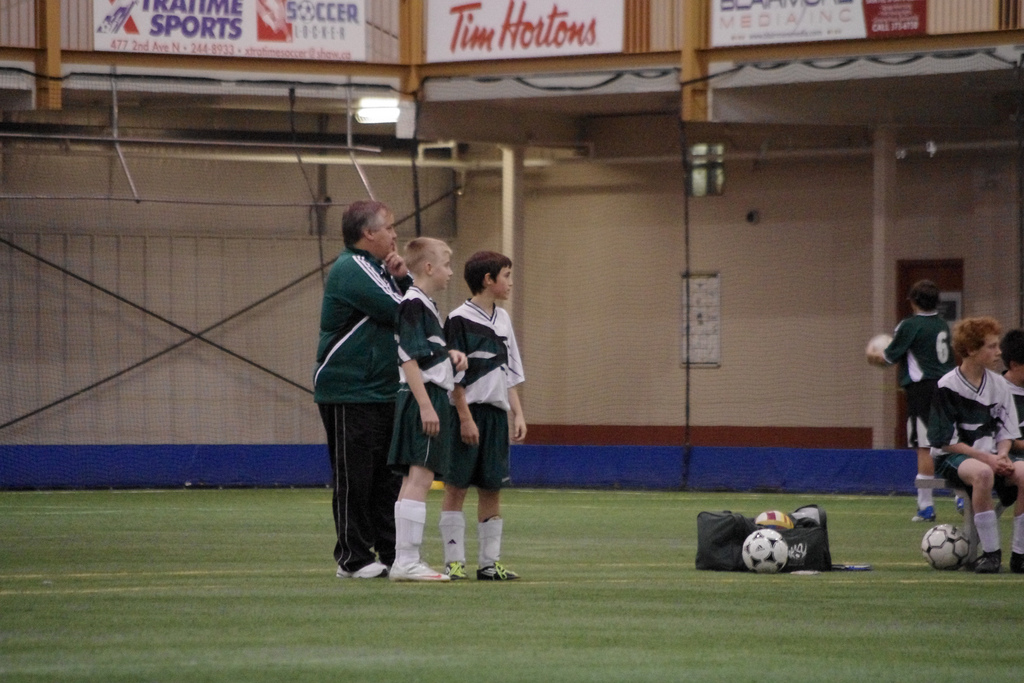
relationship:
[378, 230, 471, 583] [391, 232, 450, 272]
boy has hair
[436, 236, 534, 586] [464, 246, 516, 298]
boy has hair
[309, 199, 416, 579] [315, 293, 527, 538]
man wears uniforms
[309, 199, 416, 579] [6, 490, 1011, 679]
man in soccer field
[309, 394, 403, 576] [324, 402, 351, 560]
pants with stripes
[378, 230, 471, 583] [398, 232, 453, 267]
boy has hair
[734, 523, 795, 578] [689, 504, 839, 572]
soccer ball in bag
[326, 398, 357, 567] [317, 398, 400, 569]
stripes on pants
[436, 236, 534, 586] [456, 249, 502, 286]
boy has hair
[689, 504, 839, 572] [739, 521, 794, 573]
bag of soccer ball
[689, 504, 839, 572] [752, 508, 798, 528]
bag of soccer ball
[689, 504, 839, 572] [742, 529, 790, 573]
bag of ball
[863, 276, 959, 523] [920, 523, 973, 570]
athlete near ball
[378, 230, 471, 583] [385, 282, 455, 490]
boy in uniform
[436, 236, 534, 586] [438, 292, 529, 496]
boy in uniform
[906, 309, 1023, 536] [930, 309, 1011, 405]
athlete with hair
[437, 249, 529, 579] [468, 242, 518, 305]
boy with hair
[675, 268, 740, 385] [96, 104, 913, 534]
poster on wall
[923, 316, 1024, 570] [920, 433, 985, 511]
athlete wearing shorts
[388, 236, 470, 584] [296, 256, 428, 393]
boy wearing shirt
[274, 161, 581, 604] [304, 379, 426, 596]
man wearing pants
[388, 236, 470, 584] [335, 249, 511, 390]
boy wearing shirt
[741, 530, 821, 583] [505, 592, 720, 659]
ball on ground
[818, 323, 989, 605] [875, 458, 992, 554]
athlete sitting bench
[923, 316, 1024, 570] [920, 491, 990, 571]
athlete holding ball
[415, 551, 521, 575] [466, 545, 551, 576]
sneakers with shoelaces